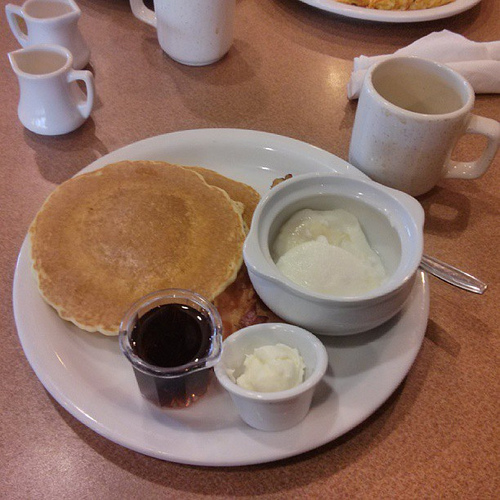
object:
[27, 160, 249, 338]
pancake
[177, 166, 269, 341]
pancake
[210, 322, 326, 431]
container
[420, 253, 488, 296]
spoon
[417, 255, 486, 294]
silverware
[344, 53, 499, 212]
coffee mug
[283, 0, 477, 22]
plate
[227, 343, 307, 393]
butter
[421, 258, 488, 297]
handle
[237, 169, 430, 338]
bowl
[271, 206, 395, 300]
butter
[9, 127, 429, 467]
plate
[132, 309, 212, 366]
syrup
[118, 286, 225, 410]
container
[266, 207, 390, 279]
grits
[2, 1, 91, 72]
pitcher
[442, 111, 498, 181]
handle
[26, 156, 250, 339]
breakfast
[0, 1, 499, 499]
table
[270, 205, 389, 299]
egg whites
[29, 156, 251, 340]
food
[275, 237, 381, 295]
food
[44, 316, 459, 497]
shadow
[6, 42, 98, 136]
cup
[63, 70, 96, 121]
handle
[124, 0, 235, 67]
coffe cup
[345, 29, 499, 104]
napkin